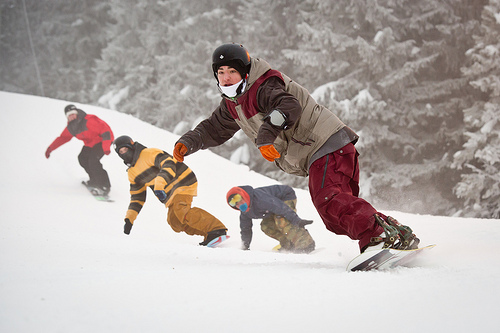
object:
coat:
[174, 57, 359, 178]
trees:
[3, 0, 499, 214]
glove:
[257, 142, 280, 162]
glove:
[173, 142, 193, 162]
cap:
[211, 43, 251, 83]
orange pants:
[166, 195, 228, 236]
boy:
[111, 135, 228, 246]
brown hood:
[114, 134, 196, 224]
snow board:
[81, 182, 116, 205]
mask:
[118, 149, 137, 162]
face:
[115, 145, 133, 160]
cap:
[109, 135, 135, 157]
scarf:
[216, 78, 252, 100]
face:
[216, 63, 245, 94]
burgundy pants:
[307, 141, 397, 249]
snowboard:
[208, 231, 230, 248]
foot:
[198, 230, 227, 245]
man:
[44, 95, 118, 200]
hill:
[0, 89, 497, 331]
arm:
[191, 99, 240, 153]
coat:
[125, 144, 201, 225]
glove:
[45, 148, 48, 155]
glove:
[104, 149, 111, 155]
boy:
[171, 43, 418, 248]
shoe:
[346, 220, 399, 272]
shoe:
[386, 220, 420, 248]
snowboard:
[345, 243, 447, 269]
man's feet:
[338, 228, 401, 272]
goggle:
[229, 193, 240, 206]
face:
[228, 190, 248, 211]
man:
[225, 183, 316, 253]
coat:
[237, 183, 303, 248]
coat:
[47, 110, 114, 154]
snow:
[295, 11, 407, 109]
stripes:
[145, 153, 195, 199]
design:
[215, 236, 223, 246]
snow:
[56, 252, 216, 320]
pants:
[75, 142, 109, 189]